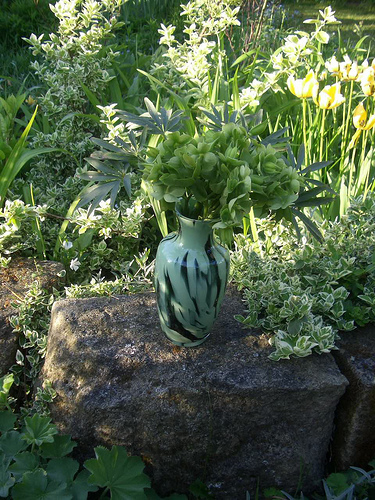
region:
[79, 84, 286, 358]
Vase sitting on concrete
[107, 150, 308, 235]
Leafy plants inside the vase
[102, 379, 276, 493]
The rock has moss on it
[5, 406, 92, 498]
Leaves growing beside the rock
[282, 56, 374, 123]
Yellow flowers in the background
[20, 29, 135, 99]
green and white leafy bush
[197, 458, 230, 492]
White mark on the rock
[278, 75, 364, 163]
The flowers have a long thin stem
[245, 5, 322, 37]
Purple flowers in the background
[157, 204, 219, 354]
The vase is made of glass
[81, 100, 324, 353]
green plants in vase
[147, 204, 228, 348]
dark green and white vase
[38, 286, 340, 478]
stone that vase is resting on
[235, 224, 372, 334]
green plant growing on stone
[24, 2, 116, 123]
tall plant growing in grass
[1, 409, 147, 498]
cluster of green leaves in grass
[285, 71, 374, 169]
yellow flowers in green grass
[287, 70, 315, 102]
yellow flower petals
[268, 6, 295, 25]
blue flowers in green grass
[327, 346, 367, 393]
crack between two stones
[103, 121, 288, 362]
Vase on the rock.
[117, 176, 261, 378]
Green and dark green vase.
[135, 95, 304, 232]
Leaves in the vase.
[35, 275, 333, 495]
Rock on the ground.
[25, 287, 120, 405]
Sunlight on the rock.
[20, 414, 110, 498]
Plants by the rock.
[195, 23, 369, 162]
Flowers in the background.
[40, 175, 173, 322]
Plants on the ground.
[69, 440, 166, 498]
Leaves on the plant.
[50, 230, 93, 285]
White flower on the plant.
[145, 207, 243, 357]
green vase is on grey stone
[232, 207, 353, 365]
green plant is next to vase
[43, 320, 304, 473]
stone is square and grey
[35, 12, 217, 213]
white plants behind grey rock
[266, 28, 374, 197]
yellow flowers on plants behind rock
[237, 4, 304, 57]
lavender blooms on plants in background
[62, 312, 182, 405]
white spots on brown rock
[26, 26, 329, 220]
numerous plants in group behind rock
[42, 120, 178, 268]
thick green fronds on plants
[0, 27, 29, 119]
tall green grasses in background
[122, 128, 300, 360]
vase with a green plant in it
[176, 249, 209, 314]
black line on the vase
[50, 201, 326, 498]
vase sitting on a rock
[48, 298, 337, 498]
large, swuare rock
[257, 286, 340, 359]
green and white leaves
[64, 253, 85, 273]
small white flower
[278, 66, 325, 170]
yellow flower with a long green stem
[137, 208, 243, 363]
cream and black vase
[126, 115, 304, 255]
thick green leaves sticking out of the top of the vase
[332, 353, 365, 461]
division between the rocks